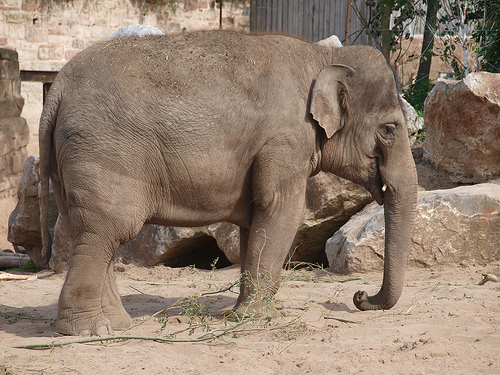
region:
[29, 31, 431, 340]
a elephant in the sand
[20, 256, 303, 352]
a twig of a tree limb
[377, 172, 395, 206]
small white tusk on trunk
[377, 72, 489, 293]
large gray and brown boulder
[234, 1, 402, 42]
a metal shed behind elephant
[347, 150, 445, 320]
a elephant trunk on the ground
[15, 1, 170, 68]
a brick building behind elephant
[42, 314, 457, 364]
light tan sand under the elephant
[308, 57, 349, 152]
ear of a elephant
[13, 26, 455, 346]
a small baby elephant standing on the sand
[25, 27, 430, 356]
large brown elephant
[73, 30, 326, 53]
hair on the elephants back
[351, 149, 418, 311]
Elephants brown trunk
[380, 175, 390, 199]
stick in the elephants mouth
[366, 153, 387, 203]
brown elephants mouth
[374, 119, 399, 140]
elephants eye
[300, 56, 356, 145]
elephants ear on brown elephant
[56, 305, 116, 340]
brown elephants hoof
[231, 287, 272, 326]
brown elephants hoof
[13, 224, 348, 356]
stick on ground next to elephant with a few green leaves on it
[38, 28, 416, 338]
Smaller then average elephant standing in dirt.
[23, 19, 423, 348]
a small elephant on the sand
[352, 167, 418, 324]
a elephants trunk on the ground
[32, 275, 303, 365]
a small tree limb on the ground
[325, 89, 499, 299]
a couple of gray boulders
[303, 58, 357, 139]
a elephants gray ear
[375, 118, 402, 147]
a elephants brown eye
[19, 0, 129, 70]
a brick wall behind the elephant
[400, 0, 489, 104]
a leafy green tree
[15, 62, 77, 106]
a wooden fence with a post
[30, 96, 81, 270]
A elephants gray tail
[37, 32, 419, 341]
Gray elephant in forefront.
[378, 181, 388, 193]
White tusk on elephant.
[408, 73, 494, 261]
Large tan rocks in the background.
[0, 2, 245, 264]
Brick building behind elephant.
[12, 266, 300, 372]
Twig branch on ground in forefront.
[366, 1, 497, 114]
Trees in the background.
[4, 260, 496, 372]
Sand on the ground.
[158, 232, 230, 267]
Hole in the rocks.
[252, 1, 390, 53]
Wood fence in the background.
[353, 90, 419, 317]
Gray elephant trunk.